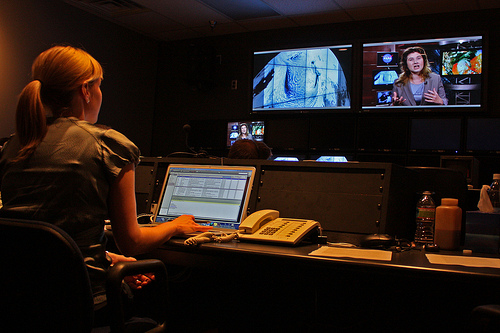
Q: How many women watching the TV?
A: One.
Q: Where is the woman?
A: At her work station.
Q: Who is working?
A: A woman.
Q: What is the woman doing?
A: Working.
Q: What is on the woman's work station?
A: A telephone and laptop.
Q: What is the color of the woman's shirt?
A: Gray.